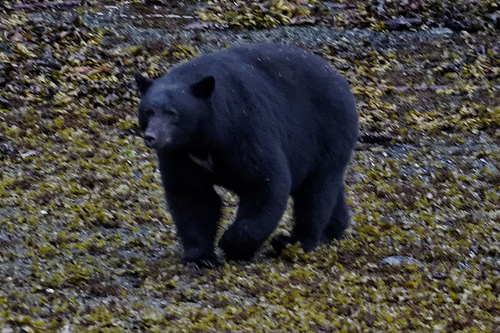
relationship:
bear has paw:
[132, 40, 360, 267] [181, 249, 218, 269]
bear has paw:
[132, 40, 360, 267] [220, 238, 254, 265]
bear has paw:
[132, 40, 360, 267] [276, 241, 305, 258]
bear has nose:
[132, 40, 360, 267] [143, 129, 155, 149]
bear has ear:
[132, 40, 360, 267] [190, 77, 216, 101]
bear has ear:
[132, 40, 360, 267] [131, 71, 153, 93]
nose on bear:
[143, 129, 155, 149] [132, 40, 360, 267]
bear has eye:
[132, 40, 360, 267] [163, 109, 177, 119]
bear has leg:
[132, 40, 360, 267] [231, 167, 292, 244]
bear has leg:
[132, 40, 360, 267] [157, 161, 224, 244]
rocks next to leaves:
[176, 300, 201, 317] [54, 141, 171, 263]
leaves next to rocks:
[54, 141, 171, 263] [176, 300, 201, 317]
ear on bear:
[190, 77, 216, 101] [132, 40, 360, 267]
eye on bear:
[163, 109, 177, 119] [132, 40, 360, 267]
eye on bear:
[144, 110, 157, 116] [132, 40, 360, 267]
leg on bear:
[157, 161, 224, 244] [132, 40, 360, 267]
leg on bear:
[231, 167, 292, 244] [132, 40, 360, 267]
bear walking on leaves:
[132, 40, 360, 267] [54, 141, 171, 263]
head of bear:
[142, 80, 205, 151] [132, 40, 360, 267]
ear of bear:
[190, 77, 216, 101] [132, 40, 360, 267]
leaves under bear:
[54, 141, 171, 263] [132, 40, 360, 267]